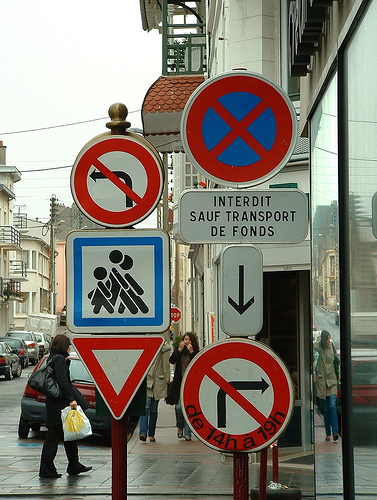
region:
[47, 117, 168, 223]
street sign pointing left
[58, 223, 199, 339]
street sign showing people walking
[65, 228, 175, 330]
blue, black and white street sign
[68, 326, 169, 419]
street sign in the shape of a triangle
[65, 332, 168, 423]
red and white street sign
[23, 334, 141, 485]
a woman walking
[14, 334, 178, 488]
a woman walking across the road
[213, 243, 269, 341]
a black arrow pointing down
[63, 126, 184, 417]
three types of street signs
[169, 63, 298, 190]
a round street sign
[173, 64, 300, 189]
The sign is round.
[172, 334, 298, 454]
The sign is round.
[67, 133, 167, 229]
The sign is round.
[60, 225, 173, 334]
The sign is square.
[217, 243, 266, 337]
The sign is rectangular.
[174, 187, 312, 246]
The sign is rectangular.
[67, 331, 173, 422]
The sign is triangular.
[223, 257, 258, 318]
The arrow is black.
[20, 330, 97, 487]
The woman is carrying a bag.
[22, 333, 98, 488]
The woman has a shoulder bag.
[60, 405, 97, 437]
the shopping bag is white and yellow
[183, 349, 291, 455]
the street sign is a circle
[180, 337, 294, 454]
the sign prohibits a right turn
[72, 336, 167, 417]
the street sign is red and white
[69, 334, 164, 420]
the yield sign is a triangle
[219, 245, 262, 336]
the arrow is pointing downwards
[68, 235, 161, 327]
the sign contains black, white, and blue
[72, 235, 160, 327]
the sign shows that people are walking nearby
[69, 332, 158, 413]
red and white pyramid sign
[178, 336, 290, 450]
black, red and white sign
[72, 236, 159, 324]
black, blue and white square sign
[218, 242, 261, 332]
white and black oblong sign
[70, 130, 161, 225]
red, white and black directional sign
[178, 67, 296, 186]
blue, red and white sign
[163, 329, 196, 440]
woman walking down the street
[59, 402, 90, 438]
white and yellow bag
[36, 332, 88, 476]
woman crossing the street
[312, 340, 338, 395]
rain coat woman is wearing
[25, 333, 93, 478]
Person walking on the street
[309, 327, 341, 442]
Person's reflection on the glass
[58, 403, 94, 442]
White plastic bag carried by the person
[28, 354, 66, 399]
Blag shoulder bag carried by the person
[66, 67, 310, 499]
Two street signs on the street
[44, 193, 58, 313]
Brown telephone pole on the street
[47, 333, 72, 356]
Head of the person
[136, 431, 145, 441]
right foot of the person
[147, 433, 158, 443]
left foot of the person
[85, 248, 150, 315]
Black drawing on the street sign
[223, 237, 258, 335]
Arrow on a sign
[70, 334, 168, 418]
Triangle shaped street sign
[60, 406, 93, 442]
White and yellow bag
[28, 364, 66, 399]
Black purse on woman's shoulder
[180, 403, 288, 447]
Writing on a sign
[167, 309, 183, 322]
Stop sign in the background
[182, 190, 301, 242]
Writing on a sign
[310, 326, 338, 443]
Reflection on a building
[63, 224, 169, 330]
Pedestrian crossing road sign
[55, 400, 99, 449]
Plastic shopping bag being carried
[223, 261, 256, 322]
black arrow pointing down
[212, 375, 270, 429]
black arrow pointing to the right